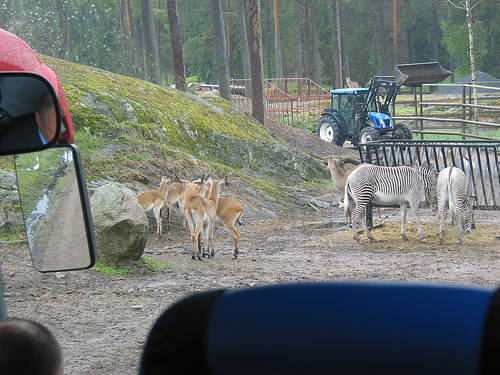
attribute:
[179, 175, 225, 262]
antelope — brown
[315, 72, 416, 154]
tractor — bright blue, blue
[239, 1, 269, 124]
tree — tall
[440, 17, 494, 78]
leaves — green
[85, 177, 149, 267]
rock — grey, large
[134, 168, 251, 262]
antelopes — brown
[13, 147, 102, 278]
mirror — side view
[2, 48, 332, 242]
rock — large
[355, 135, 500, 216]
feeder — black, metal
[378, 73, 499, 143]
fence — tall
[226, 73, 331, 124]
metal — red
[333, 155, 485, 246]
zebras — feeding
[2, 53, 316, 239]
grass — dry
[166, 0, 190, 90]
tree — tall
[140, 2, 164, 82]
tree — tall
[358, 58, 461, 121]
crane — up